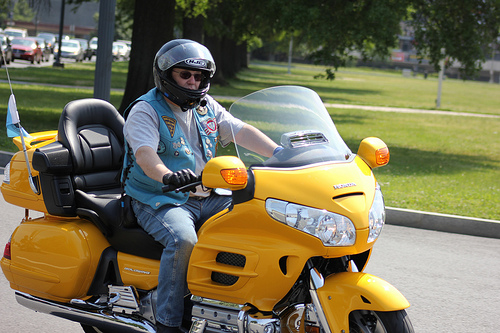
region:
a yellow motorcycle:
[4, 52, 456, 331]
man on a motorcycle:
[102, 36, 308, 331]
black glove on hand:
[158, 164, 212, 211]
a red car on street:
[6, 28, 48, 79]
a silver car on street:
[49, 35, 93, 70]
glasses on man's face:
[177, 67, 211, 84]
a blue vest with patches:
[106, 80, 241, 215]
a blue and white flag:
[3, 90, 33, 155]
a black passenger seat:
[42, 92, 143, 219]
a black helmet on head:
[147, 33, 218, 120]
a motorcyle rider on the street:
[13, 25, 467, 325]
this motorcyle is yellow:
[5, 108, 429, 322]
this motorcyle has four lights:
[217, 141, 407, 250]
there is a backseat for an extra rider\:
[35, 93, 157, 230]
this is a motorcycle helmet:
[132, 28, 225, 109]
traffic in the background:
[4, 6, 143, 78]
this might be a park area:
[35, 40, 498, 212]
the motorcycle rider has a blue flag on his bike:
[3, 78, 34, 148]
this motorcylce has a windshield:
[222, 83, 369, 174]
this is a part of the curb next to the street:
[343, 186, 498, 247]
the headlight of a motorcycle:
[265, 194, 358, 244]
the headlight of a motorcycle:
[366, 179, 388, 246]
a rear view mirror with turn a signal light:
[205, 155, 251, 197]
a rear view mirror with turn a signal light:
[356, 133, 396, 168]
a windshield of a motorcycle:
[231, 80, 359, 172]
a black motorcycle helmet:
[146, 35, 215, 110]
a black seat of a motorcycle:
[51, 92, 123, 215]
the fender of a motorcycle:
[326, 276, 404, 315]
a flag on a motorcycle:
[5, 91, 45, 190]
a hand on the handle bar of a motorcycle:
[158, 169, 202, 199]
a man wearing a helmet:
[132, 20, 226, 119]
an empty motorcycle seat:
[27, 59, 130, 235]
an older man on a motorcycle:
[108, 7, 295, 332]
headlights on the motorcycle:
[250, 185, 397, 247]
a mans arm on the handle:
[133, 141, 253, 203]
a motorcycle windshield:
[209, 72, 368, 174]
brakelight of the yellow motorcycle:
[0, 224, 44, 291]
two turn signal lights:
[184, 125, 399, 197]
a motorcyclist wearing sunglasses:
[131, 31, 240, 138]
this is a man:
[140, 50, 202, 241]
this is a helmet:
[157, 39, 211, 64]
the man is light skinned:
[141, 150, 156, 175]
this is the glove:
[163, 167, 192, 179]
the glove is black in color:
[173, 167, 185, 177]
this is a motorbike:
[219, 164, 407, 311]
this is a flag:
[5, 93, 36, 136]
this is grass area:
[403, 102, 485, 209]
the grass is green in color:
[432, 121, 469, 174]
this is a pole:
[94, 16, 124, 74]